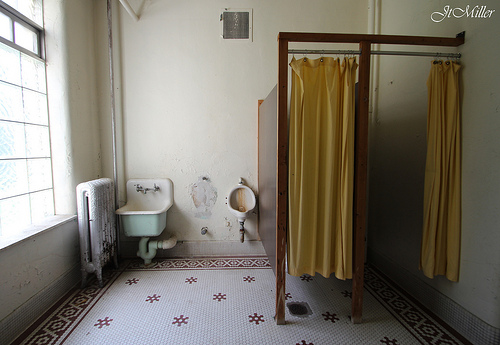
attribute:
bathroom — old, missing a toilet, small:
[1, 0, 500, 344]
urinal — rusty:
[226, 179, 259, 242]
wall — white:
[96, 3, 371, 260]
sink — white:
[115, 179, 180, 264]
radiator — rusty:
[76, 176, 122, 286]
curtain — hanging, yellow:
[289, 53, 351, 284]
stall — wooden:
[253, 31, 474, 329]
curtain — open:
[421, 53, 464, 284]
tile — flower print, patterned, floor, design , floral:
[8, 256, 480, 344]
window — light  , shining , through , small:
[1, 1, 51, 63]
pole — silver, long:
[106, 2, 123, 268]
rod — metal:
[283, 44, 460, 61]